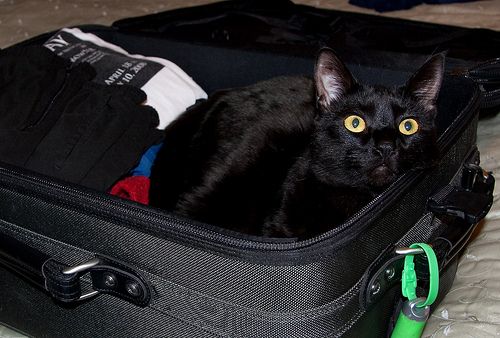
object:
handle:
[5, 216, 158, 315]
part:
[479, 263, 491, 281]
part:
[482, 136, 494, 153]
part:
[450, 315, 483, 330]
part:
[489, 308, 495, 329]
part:
[452, 291, 465, 311]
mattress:
[2, 0, 498, 337]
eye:
[396, 117, 418, 137]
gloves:
[0, 58, 163, 193]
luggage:
[0, 5, 470, 249]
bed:
[0, 0, 500, 337]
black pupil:
[352, 118, 359, 127]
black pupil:
[404, 121, 412, 131]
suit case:
[0, 0, 498, 338]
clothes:
[0, 51, 163, 191]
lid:
[109, 0, 499, 116]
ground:
[445, 145, 498, 170]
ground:
[322, 74, 368, 115]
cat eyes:
[344, 115, 367, 135]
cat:
[148, 47, 449, 238]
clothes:
[32, 25, 207, 133]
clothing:
[135, 141, 162, 182]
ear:
[410, 50, 447, 109]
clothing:
[109, 173, 150, 204]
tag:
[394, 240, 439, 309]